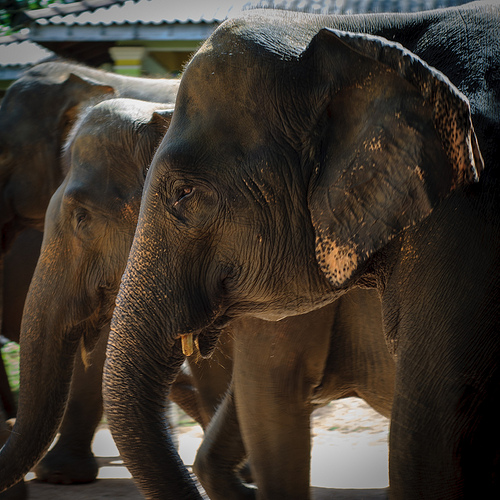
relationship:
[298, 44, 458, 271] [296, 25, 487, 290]
dirt on ear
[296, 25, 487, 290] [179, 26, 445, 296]
ear of elephant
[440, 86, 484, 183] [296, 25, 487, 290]
dirt on ear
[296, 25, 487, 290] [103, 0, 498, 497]
ear of elephant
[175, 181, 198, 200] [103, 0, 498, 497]
eye of elephant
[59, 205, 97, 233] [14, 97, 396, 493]
eye of elephant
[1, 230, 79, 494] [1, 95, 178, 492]
trunk of elephant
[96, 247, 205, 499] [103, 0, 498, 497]
trunk of elephant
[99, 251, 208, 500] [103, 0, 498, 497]
trunk of elephant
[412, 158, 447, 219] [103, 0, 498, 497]
ground under elephant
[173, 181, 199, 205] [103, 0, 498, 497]
eye of elephant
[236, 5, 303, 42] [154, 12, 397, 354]
light hitting head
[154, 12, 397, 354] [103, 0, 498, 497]
head of elephant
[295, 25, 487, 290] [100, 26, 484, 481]
ear of elephant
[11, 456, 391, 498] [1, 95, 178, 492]
shadow of elephant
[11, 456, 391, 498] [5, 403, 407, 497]
shadow on ground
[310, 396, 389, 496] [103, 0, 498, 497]
dirt beneath elephant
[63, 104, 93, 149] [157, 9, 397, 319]
elephant hair on head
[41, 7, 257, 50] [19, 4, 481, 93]
roof of house